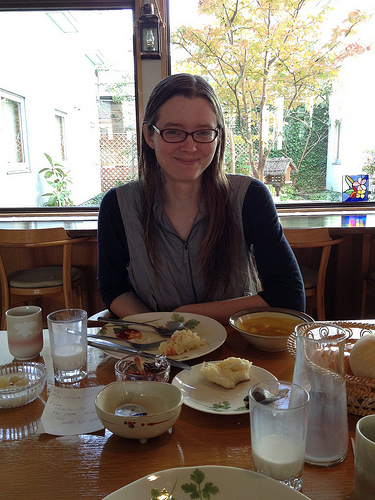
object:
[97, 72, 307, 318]
smiling woman